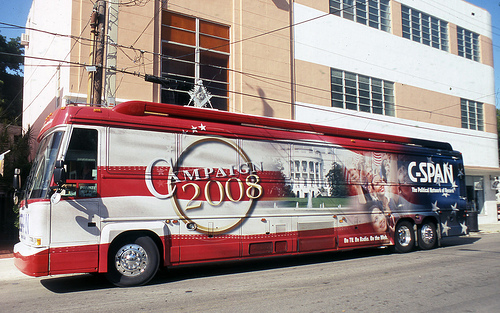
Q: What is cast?
A: Shadow.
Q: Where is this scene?
A: Street.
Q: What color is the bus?
A: Red and white.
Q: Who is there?
A: No one.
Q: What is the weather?
A: Sunny.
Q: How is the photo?
A: Clear.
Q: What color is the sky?
A: Blue.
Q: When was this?
A: Daytime.